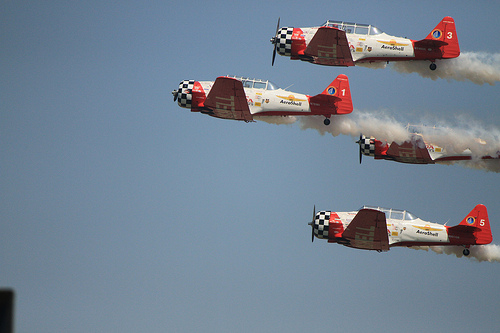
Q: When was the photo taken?
A: Daytime.